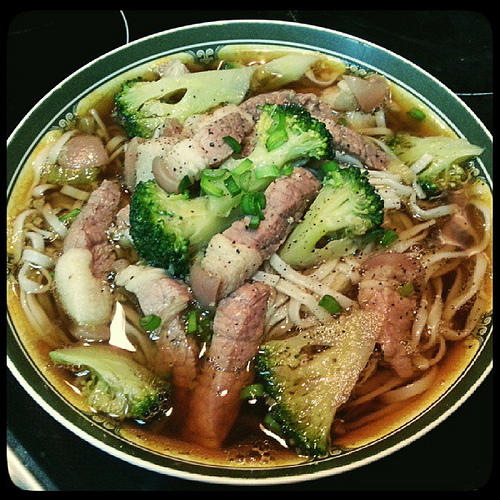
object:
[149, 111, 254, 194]
food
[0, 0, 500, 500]
table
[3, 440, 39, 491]
shadow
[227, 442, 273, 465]
bubbles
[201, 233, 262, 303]
fat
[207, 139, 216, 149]
pepper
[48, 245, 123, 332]
florets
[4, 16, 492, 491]
bowl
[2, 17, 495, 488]
rim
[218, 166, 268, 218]
center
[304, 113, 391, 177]
steak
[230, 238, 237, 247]
seasoning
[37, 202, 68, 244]
noodles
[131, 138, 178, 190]
water chestnut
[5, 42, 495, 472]
broth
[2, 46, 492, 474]
chinese food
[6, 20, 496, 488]
dish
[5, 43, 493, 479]
sauce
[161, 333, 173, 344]
pepper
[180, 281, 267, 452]
beef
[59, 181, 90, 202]
egg noodles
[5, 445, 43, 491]
fork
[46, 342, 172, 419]
broccoli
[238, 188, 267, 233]
pork piece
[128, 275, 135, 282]
pepper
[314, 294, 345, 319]
piece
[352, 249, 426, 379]
meat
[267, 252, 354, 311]
asian noodle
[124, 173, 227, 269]
vegetables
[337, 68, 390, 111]
onion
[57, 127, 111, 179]
mushroom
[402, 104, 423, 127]
chive